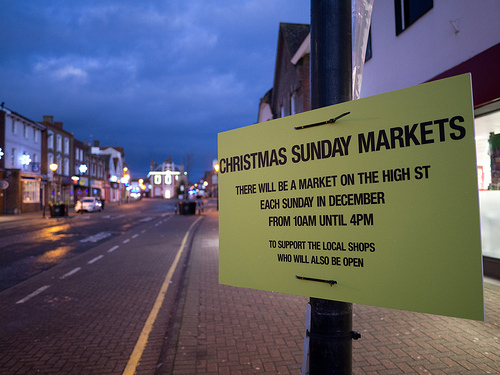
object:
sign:
[214, 69, 484, 322]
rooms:
[163, 175, 175, 184]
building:
[146, 150, 188, 198]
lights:
[18, 154, 32, 165]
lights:
[78, 162, 88, 173]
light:
[49, 163, 57, 204]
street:
[0, 200, 203, 372]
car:
[75, 197, 103, 213]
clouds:
[25, 2, 260, 121]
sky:
[1, 0, 238, 117]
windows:
[3, 116, 118, 182]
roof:
[277, 20, 313, 57]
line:
[121, 213, 206, 374]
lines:
[13, 206, 178, 308]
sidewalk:
[170, 199, 499, 374]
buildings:
[0, 103, 125, 219]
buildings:
[255, 3, 499, 282]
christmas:
[219, 147, 288, 174]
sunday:
[292, 135, 353, 164]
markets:
[357, 115, 467, 154]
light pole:
[308, 0, 360, 375]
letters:
[216, 112, 469, 270]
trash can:
[178, 200, 197, 215]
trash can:
[49, 203, 66, 217]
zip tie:
[294, 110, 352, 130]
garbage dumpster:
[188, 200, 195, 203]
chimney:
[42, 110, 54, 124]